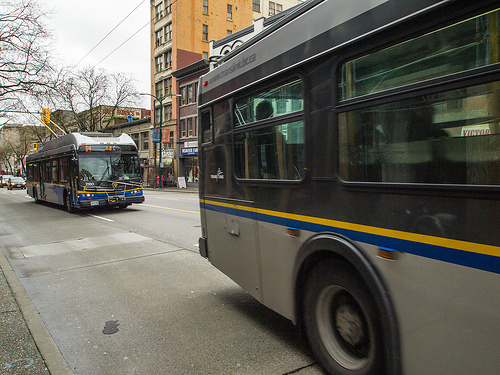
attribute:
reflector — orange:
[265, 211, 370, 252]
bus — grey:
[221, 29, 498, 253]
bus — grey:
[17, 102, 179, 221]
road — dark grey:
[34, 251, 156, 326]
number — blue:
[2, 349, 36, 373]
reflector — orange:
[371, 238, 403, 265]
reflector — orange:
[281, 223, 306, 243]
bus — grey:
[22, 126, 147, 218]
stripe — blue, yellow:
[198, 193, 497, 296]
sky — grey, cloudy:
[26, 3, 137, 102]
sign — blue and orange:
[162, 127, 170, 141]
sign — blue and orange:
[152, 130, 161, 143]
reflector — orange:
[283, 223, 300, 240]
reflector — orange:
[284, 226, 299, 236]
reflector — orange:
[375, 246, 399, 260]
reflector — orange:
[285, 228, 300, 238]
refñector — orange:
[372, 244, 402, 265]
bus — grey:
[195, 3, 499, 373]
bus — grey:
[202, 77, 402, 280]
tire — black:
[285, 236, 396, 370]